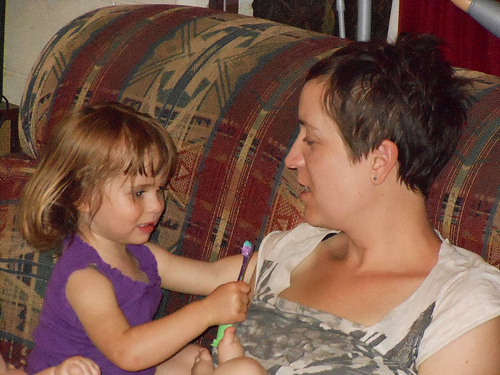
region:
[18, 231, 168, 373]
Child wearing a shirt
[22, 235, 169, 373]
Child is wearing a shirt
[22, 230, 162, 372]
Child wearing a purple shirt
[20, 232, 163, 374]
Child is wearing a purple shirt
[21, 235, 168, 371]
Girl wearing a shirt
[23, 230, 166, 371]
Girl is wearing a shirt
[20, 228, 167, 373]
Girl wearing a purple shirt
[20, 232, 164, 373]
Girl is wearing a purple shirt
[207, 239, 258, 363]
Child holding a toothbrush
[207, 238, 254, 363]
Girl holding a toothbrush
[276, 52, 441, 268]
the head of a woman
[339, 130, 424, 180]
the ear of a woman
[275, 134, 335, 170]
the nose of a woman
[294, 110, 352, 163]
the eye of a woman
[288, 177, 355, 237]
the chin of a woman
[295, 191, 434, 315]
the neck of a woman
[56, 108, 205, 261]
the head of a girl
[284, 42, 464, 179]
thw hair of a woman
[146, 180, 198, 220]
the nose of a girl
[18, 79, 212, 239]
the hair of a girl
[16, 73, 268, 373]
a young girl wearing a purple shirt holding a tooth brush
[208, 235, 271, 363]
a pruple and green toothbrush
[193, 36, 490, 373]
a woman that is looking at a child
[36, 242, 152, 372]
a purple shirt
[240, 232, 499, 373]
a whit shirt with some pictures on it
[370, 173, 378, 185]
a small earing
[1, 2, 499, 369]
a large cloth sofa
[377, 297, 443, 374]
a picture of a large tower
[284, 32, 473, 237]
the head of a woman with short black hair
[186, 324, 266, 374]
feet from a baby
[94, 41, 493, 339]
people sitting on a couch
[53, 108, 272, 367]
a girl with blond hair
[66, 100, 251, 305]
a young girl with blonde hair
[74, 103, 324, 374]
a girl holding a toothbrush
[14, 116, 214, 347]
a girl wearing a shirt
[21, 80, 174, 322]
a girl wearing a purple shirt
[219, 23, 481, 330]
a woman with short hair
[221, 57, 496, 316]
a woman with earrings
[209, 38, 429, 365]
a woman sitting on a couch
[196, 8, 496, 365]
a woman on a couch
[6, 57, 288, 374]
little girl holding a purple toothbrush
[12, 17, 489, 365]
woman sitting on couch with child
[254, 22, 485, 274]
woman with short thin dark hair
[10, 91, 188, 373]
little girl wearing a purple ruffled shirt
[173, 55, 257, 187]
teal and burgundy design on beige couch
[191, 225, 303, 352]
purple plastic toothbrush in girl's hand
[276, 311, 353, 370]
design on shirt woman is wearing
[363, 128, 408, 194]
woman's ear with small stud earring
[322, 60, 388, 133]
thinning spots in woman's dark hair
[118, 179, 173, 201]
long eyelashes on young girl